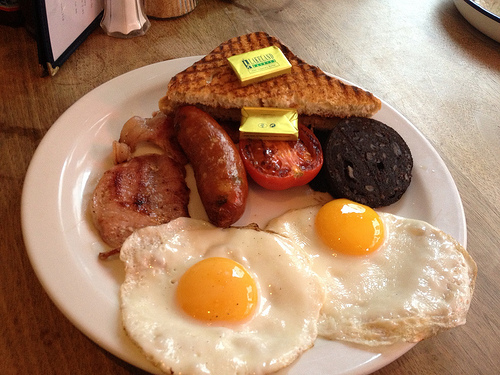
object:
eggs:
[118, 216, 326, 374]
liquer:
[363, 17, 449, 87]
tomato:
[239, 123, 323, 191]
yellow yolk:
[316, 198, 386, 257]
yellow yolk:
[173, 256, 258, 327]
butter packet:
[226, 45, 292, 87]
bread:
[158, 31, 381, 129]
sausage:
[171, 106, 248, 227]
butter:
[239, 107, 300, 142]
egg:
[263, 198, 477, 347]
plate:
[19, 55, 466, 375]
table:
[0, 0, 500, 375]